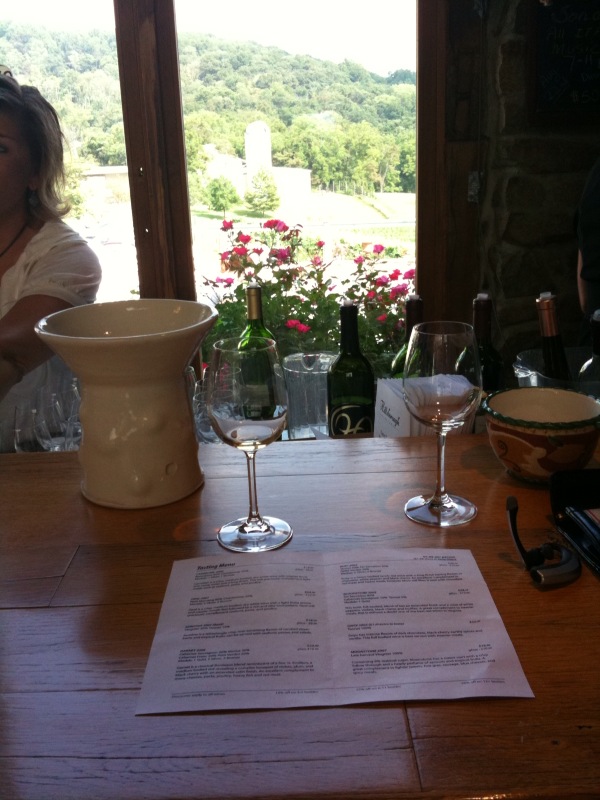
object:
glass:
[205, 336, 293, 551]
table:
[0, 433, 600, 800]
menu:
[134, 546, 536, 716]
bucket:
[34, 298, 219, 508]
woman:
[0, 63, 102, 453]